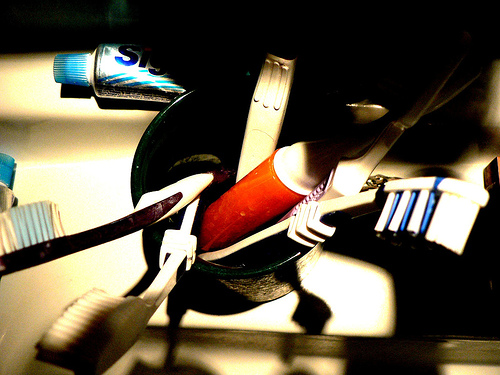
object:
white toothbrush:
[37, 292, 160, 373]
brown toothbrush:
[1, 189, 187, 278]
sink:
[1, 101, 134, 157]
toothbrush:
[200, 177, 489, 264]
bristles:
[402, 190, 434, 234]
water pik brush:
[201, 134, 364, 254]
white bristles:
[26, 286, 121, 364]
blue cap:
[53, 53, 91, 86]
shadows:
[275, 263, 333, 337]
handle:
[199, 214, 294, 261]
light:
[325, 270, 395, 337]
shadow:
[165, 269, 398, 375]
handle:
[201, 139, 306, 255]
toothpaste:
[53, 43, 183, 103]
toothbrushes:
[1, 1, 497, 374]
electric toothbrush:
[198, 48, 298, 188]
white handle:
[197, 188, 378, 265]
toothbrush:
[199, 133, 361, 250]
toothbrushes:
[0, 172, 219, 276]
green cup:
[130, 77, 336, 304]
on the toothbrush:
[197, 177, 488, 263]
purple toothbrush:
[0, 172, 208, 276]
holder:
[131, 80, 338, 313]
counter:
[0, 54, 499, 372]